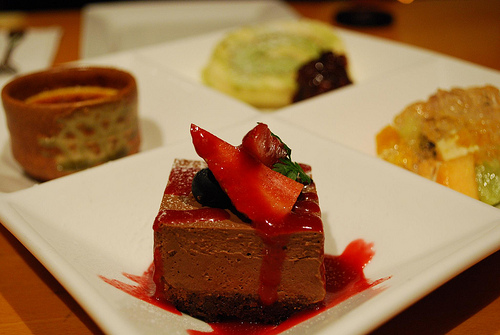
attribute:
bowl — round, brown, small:
[2, 60, 152, 191]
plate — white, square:
[1, 11, 499, 334]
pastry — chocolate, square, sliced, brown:
[145, 146, 336, 325]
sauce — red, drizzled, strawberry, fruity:
[103, 240, 384, 332]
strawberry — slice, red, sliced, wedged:
[181, 120, 306, 238]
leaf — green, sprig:
[268, 150, 313, 191]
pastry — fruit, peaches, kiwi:
[368, 73, 500, 207]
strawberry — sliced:
[233, 113, 293, 172]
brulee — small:
[204, 16, 358, 115]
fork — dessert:
[1, 23, 27, 82]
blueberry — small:
[189, 164, 236, 210]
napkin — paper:
[2, 25, 66, 91]